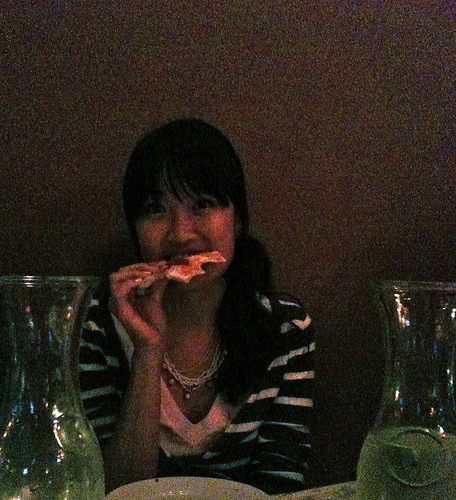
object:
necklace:
[137, 270, 231, 400]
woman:
[77, 119, 316, 496]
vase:
[0, 276, 105, 500]